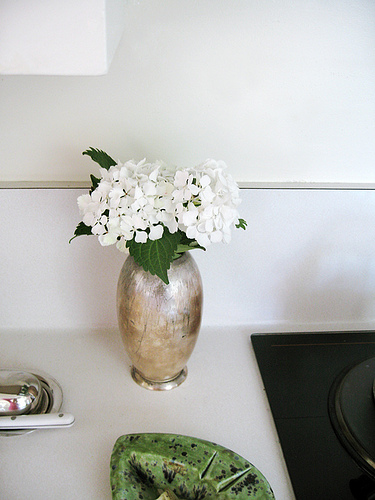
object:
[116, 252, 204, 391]
vase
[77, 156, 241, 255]
flowers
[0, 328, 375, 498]
counter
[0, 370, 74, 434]
dish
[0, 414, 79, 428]
flatware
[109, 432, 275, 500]
dish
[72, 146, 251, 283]
plant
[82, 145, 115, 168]
leaves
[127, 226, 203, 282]
leaves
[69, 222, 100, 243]
leaves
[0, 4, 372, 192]
wall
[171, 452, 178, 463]
spots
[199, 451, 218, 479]
indent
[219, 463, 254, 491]
indent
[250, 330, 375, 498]
panel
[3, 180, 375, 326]
backsplash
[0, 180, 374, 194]
edge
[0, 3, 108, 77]
cube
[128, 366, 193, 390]
base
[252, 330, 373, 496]
stove